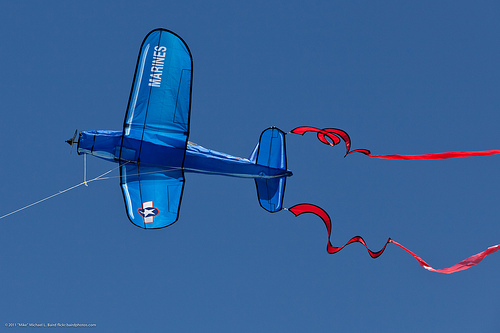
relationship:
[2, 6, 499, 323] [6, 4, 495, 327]
scene during day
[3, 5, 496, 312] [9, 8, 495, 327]
no clouds in sky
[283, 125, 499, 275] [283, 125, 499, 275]
ribbon on ribbon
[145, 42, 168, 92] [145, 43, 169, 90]
marines on kite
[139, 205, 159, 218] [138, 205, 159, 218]
star in circle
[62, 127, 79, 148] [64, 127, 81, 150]
propeller on kite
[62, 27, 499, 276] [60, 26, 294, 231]
airplane outlined black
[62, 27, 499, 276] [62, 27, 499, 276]
airplane shaped airplane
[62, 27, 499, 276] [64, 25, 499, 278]
airplane in sky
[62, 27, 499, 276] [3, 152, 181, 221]
airplane white string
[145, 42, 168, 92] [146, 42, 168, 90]
marines white logo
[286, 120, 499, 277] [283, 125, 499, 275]
long kite ribbon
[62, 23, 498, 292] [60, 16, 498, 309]
airplane flying sky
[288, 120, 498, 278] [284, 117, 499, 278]
ribbon behind airplane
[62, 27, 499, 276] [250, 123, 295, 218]
airplane back wing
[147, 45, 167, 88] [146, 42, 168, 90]
marines marines logo